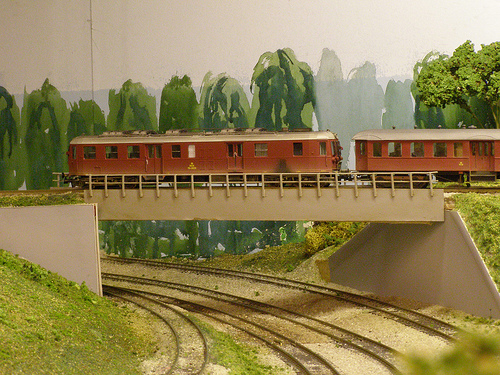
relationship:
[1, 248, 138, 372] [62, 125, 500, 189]
hillside on train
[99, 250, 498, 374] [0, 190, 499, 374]
tracks on ground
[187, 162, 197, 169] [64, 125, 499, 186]
sign on train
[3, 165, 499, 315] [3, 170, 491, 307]
bridge made of concrete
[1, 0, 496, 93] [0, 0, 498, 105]
cloud in blue sky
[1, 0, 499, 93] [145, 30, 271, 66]
cloud in sky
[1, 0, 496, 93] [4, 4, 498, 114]
cloud in sky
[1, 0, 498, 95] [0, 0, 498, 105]
white clouds in blue sky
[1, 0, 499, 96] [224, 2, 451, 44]
white clouds in blue sky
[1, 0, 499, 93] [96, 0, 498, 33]
cloud in sky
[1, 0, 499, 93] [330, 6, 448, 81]
cloud in sky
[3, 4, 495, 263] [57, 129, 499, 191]
backdrop behind train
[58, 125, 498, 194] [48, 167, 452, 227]
train on bridge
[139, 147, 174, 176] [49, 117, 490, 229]
door on train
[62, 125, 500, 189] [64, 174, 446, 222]
train over tracks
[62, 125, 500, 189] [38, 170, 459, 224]
train on bridge